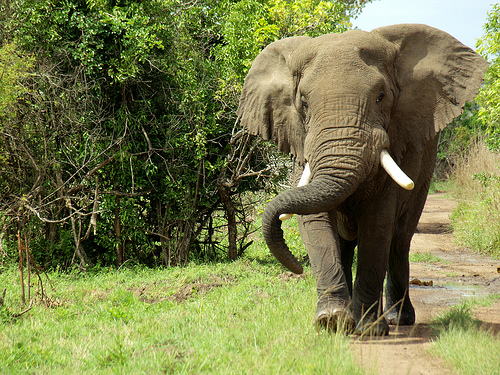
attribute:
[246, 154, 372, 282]
trunk — long, wrinkled, grey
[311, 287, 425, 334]
feet — large 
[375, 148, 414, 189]
tusk — white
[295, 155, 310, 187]
tusk — white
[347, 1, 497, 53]
sky — blue 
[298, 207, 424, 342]
legs — grey, straight, large, thick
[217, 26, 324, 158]
ear — wide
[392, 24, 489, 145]
ear — large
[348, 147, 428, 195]
tusk — white 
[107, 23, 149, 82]
leaves — green, small, shapely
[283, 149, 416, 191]
tusks — white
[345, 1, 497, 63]
clouds — white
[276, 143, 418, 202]
tusks — white, ivory, smooth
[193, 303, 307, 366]
grass — thin, green, long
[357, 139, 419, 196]
tusk — white 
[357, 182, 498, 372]
dirt path — in the wilderness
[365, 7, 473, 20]
blue sky — light blue, clear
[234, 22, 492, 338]
elephant — in the picture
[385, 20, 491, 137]
ear — elephant's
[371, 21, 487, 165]
ear — large, wide, gray, thin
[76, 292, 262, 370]
grass — green 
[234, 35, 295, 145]
ear — elephant's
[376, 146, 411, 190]
tusk — white 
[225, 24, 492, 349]
animal — large, tall, gray, wrinkled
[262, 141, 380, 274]
trunk — gray, long, wrinkled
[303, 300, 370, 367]
grass — tall 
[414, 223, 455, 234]
log — brown, thick, short